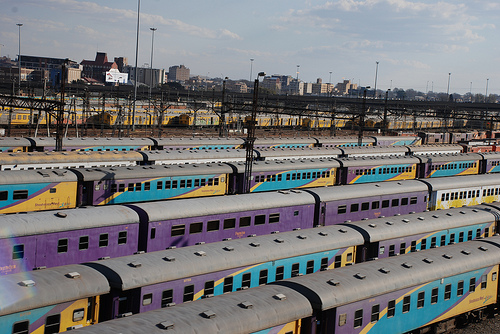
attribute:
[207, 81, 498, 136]
bridge — horizontal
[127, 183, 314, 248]
train car —  blue, gold, purple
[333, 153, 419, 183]
train car — purple, gold, blue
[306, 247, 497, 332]
train car — gold, purple, blue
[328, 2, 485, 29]
cloud — white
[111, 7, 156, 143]
poles — light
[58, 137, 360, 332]
train — multiple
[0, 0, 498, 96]
sky — blue, clouded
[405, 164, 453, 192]
ground — back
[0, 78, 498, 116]
power lines — black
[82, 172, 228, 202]
train car — purple gold, blue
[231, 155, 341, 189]
train car — purple, gold,  blue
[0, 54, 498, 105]
buildings — tall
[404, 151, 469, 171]
train car — blue, gold, purple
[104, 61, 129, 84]
billboard — white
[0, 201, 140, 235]
roof — grey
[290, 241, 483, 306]
roof — grey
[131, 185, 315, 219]
roof — grey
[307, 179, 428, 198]
roof — grey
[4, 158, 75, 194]
roof — grey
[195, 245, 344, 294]
stripe — blue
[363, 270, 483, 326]
stripe — blue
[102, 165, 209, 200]
stripe — blue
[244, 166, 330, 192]
stripe — blue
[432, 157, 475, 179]
stripe — blue